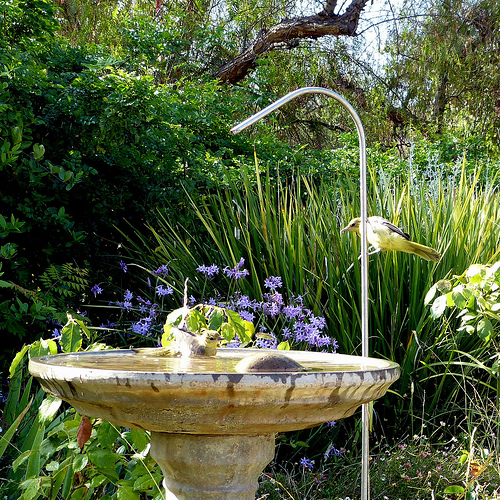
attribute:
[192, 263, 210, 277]
flower — light purple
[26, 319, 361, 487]
bird bath — stone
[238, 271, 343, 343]
flowers — blue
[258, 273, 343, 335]
flower — light purple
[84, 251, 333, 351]
flowers — purple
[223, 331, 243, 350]
flower — light purple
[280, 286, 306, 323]
flower — light purple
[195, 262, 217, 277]
flower — light purple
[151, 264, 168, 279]
flower — light purple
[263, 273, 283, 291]
flower — light purple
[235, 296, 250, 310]
flower — light purple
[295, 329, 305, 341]
flower — light purple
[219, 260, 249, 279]
flower — light purple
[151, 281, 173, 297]
flower — light purple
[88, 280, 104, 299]
flower — light purple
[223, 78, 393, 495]
crook — silver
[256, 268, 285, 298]
flower — light purple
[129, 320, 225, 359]
bird — black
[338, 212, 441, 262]
bird — black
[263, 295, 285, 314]
flower — light purple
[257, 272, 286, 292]
flower — light purple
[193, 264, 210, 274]
flower — light purple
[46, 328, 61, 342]
flower — light purple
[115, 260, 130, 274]
flower — light purple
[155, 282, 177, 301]
flower — light purple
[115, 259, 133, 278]
flower — light purple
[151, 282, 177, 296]
flower — light purple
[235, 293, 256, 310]
flower — light purple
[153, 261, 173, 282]
flower — light purple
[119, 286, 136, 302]
flower — light purple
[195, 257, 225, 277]
flower — light purple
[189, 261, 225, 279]
flower — light purple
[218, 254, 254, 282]
flower — light purple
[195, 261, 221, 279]
flower — blue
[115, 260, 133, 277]
flower — blue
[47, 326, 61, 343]
flower — blue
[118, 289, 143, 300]
flower — blue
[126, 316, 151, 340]
flower — blue